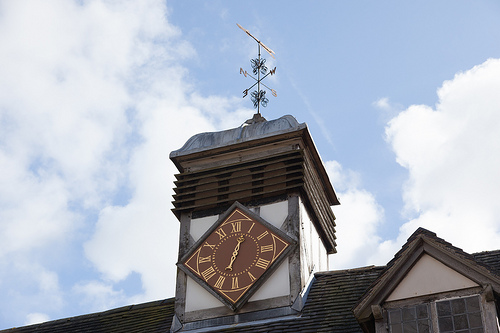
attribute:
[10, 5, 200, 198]
cloud — white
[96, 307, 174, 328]
shingles — black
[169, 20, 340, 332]
tower — top , home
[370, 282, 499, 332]
window — glass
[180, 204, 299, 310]
clock — diamond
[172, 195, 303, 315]
clock — diamond shaped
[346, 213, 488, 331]
home — top part 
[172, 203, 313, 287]
hands — golden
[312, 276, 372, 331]
roof — wooden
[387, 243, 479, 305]
wall — white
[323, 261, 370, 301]
roof — grey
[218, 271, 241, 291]
numerals — gold roman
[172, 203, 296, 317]
clock — square